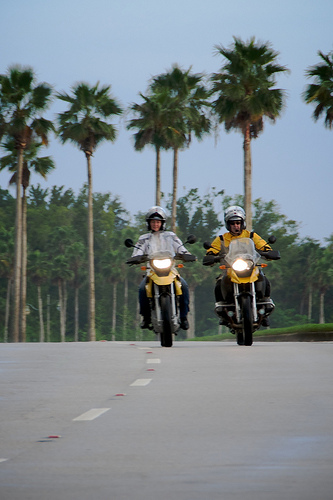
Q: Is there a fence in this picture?
A: No, there are no fences.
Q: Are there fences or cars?
A: No, there are no fences or cars.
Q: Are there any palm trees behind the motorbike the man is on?
A: Yes, there is a palm tree behind the motorcycle.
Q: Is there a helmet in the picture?
A: Yes, there is a helmet.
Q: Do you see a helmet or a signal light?
A: Yes, there is a helmet.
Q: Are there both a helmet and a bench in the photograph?
A: No, there is a helmet but no benches.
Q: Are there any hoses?
A: No, there are no hoses.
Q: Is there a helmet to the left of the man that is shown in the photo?
A: Yes, there is a helmet to the left of the man.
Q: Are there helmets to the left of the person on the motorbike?
A: Yes, there is a helmet to the left of the man.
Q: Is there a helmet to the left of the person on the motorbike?
A: Yes, there is a helmet to the left of the man.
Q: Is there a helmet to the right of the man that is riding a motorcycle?
A: No, the helmet is to the left of the man.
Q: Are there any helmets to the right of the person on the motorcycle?
A: No, the helmet is to the left of the man.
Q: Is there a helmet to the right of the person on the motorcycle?
A: No, the helmet is to the left of the man.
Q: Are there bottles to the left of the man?
A: No, there is a helmet to the left of the man.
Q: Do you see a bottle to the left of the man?
A: No, there is a helmet to the left of the man.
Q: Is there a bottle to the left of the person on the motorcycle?
A: No, there is a helmet to the left of the man.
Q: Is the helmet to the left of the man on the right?
A: Yes, the helmet is to the left of the man.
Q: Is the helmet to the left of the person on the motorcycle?
A: Yes, the helmet is to the left of the man.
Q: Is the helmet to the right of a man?
A: No, the helmet is to the left of a man.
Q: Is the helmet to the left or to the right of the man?
A: The helmet is to the left of the man.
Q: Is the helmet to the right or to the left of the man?
A: The helmet is to the left of the man.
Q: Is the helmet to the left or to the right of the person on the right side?
A: The helmet is to the left of the man.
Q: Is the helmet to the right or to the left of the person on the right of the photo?
A: The helmet is to the left of the man.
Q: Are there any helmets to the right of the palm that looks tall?
A: Yes, there is a helmet to the right of the palm.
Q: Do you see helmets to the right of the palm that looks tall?
A: Yes, there is a helmet to the right of the palm.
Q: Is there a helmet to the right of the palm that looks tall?
A: Yes, there is a helmet to the right of the palm.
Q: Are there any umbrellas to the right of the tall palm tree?
A: No, there is a helmet to the right of the palm tree.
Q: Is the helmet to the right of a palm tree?
A: Yes, the helmet is to the right of a palm tree.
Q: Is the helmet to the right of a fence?
A: No, the helmet is to the right of a palm tree.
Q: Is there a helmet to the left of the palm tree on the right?
A: Yes, there is a helmet to the left of the palm.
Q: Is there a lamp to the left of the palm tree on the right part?
A: No, there is a helmet to the left of the palm.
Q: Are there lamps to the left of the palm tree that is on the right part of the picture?
A: No, there is a helmet to the left of the palm.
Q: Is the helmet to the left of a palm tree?
A: Yes, the helmet is to the left of a palm tree.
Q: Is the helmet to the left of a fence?
A: No, the helmet is to the left of a palm tree.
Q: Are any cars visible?
A: No, there are no cars.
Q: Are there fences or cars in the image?
A: No, there are no cars or fences.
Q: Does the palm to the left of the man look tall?
A: Yes, the palm is tall.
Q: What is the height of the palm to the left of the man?
A: The palm tree is tall.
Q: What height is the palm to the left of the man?
A: The palm tree is tall.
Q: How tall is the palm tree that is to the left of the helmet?
A: The palm is tall.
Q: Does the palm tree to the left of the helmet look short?
A: No, the palm is tall.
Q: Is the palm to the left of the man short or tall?
A: The palm is tall.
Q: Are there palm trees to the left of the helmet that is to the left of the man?
A: Yes, there is a palm tree to the left of the helmet.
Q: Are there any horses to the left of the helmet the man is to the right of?
A: No, there is a palm tree to the left of the helmet.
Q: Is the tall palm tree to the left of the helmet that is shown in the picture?
A: Yes, the palm is to the left of the helmet.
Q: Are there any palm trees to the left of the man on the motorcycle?
A: Yes, there is a palm tree to the left of the man.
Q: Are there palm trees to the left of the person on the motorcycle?
A: Yes, there is a palm tree to the left of the man.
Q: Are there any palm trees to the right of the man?
A: No, the palm tree is to the left of the man.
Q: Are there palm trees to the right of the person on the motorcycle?
A: No, the palm tree is to the left of the man.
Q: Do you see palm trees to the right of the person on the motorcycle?
A: No, the palm tree is to the left of the man.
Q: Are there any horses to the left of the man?
A: No, there is a palm tree to the left of the man.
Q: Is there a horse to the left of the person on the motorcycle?
A: No, there is a palm tree to the left of the man.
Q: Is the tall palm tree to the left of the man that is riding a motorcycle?
A: Yes, the palm is to the left of the man.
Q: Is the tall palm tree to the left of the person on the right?
A: Yes, the palm is to the left of the man.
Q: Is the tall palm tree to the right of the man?
A: No, the palm tree is to the left of the man.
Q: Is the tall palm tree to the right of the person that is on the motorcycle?
A: No, the palm tree is to the left of the man.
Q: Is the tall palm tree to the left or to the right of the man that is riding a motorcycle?
A: The palm tree is to the left of the man.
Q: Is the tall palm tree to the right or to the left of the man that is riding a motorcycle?
A: The palm tree is to the left of the man.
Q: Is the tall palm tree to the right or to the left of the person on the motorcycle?
A: The palm tree is to the left of the man.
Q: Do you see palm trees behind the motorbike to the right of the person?
A: Yes, there is a palm tree behind the motorcycle.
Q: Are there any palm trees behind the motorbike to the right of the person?
A: Yes, there is a palm tree behind the motorcycle.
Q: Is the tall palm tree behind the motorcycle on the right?
A: Yes, the palm is behind the motorbike.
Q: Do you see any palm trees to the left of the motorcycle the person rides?
A: Yes, there is a palm tree to the left of the motorbike.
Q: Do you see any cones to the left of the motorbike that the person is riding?
A: No, there is a palm tree to the left of the motorbike.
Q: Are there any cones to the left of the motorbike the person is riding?
A: No, there is a palm tree to the left of the motorbike.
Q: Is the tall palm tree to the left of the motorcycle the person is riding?
A: Yes, the palm is to the left of the motorcycle.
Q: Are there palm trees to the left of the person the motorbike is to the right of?
A: Yes, there is a palm tree to the left of the person.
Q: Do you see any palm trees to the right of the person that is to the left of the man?
A: No, the palm tree is to the left of the person.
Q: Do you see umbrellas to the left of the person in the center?
A: No, there is a palm tree to the left of the person.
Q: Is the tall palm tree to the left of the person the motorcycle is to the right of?
A: Yes, the palm tree is to the left of the person.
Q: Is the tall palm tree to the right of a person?
A: No, the palm is to the left of a person.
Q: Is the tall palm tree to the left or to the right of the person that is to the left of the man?
A: The palm is to the left of the person.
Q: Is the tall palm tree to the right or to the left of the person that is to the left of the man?
A: The palm is to the left of the person.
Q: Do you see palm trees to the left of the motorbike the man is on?
A: Yes, there is a palm tree to the left of the motorcycle.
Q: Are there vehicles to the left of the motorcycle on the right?
A: No, there is a palm tree to the left of the motorbike.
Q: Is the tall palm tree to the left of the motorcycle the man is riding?
A: Yes, the palm is to the left of the motorbike.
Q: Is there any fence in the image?
A: No, there are no fences.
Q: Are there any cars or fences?
A: No, there are no fences or cars.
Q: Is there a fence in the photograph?
A: No, there are no fences.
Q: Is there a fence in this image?
A: No, there are no fences.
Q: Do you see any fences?
A: No, there are no fences.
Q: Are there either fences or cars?
A: No, there are no fences or cars.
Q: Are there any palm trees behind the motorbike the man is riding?
A: Yes, there is a palm tree behind the motorcycle.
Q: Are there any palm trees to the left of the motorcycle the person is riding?
A: Yes, there is a palm tree to the left of the motorcycle.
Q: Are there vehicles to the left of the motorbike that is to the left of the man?
A: No, there is a palm tree to the left of the motorbike.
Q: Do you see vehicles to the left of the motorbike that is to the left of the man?
A: No, there is a palm tree to the left of the motorbike.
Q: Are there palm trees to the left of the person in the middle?
A: Yes, there is a palm tree to the left of the person.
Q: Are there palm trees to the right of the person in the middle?
A: No, the palm tree is to the left of the person.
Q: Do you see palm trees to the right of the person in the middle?
A: No, the palm tree is to the left of the person.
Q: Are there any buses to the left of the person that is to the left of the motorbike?
A: No, there is a palm tree to the left of the person.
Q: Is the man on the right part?
A: Yes, the man is on the right of the image.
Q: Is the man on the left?
A: No, the man is on the right of the image.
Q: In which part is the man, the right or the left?
A: The man is on the right of the image.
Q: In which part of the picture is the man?
A: The man is on the right of the image.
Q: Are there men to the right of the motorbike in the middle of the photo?
A: Yes, there is a man to the right of the motorbike.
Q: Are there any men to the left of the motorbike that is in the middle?
A: No, the man is to the right of the motorbike.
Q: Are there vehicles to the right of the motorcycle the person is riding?
A: No, there is a man to the right of the motorcycle.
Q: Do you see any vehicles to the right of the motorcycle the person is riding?
A: No, there is a man to the right of the motorcycle.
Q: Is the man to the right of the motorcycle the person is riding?
A: Yes, the man is to the right of the motorcycle.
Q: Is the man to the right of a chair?
A: No, the man is to the right of the motorcycle.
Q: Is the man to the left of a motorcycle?
A: No, the man is to the right of a motorcycle.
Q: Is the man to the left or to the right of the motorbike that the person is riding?
A: The man is to the right of the motorbike.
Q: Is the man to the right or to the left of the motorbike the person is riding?
A: The man is to the right of the motorbike.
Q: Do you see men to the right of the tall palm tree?
A: Yes, there is a man to the right of the palm.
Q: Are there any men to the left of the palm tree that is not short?
A: No, the man is to the right of the palm.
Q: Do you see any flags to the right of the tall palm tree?
A: No, there is a man to the right of the palm.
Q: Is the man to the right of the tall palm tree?
A: Yes, the man is to the right of the palm tree.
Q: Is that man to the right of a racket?
A: No, the man is to the right of the palm tree.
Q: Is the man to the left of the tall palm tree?
A: No, the man is to the right of the palm tree.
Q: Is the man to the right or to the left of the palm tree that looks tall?
A: The man is to the right of the palm tree.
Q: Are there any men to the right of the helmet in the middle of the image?
A: Yes, there is a man to the right of the helmet.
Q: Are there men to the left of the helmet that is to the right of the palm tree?
A: No, the man is to the right of the helmet.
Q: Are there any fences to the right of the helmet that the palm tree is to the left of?
A: No, there is a man to the right of the helmet.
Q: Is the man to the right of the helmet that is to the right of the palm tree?
A: Yes, the man is to the right of the helmet.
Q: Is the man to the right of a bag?
A: No, the man is to the right of the helmet.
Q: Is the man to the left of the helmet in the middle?
A: No, the man is to the right of the helmet.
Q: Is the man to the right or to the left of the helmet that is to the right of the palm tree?
A: The man is to the right of the helmet.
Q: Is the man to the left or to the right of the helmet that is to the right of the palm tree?
A: The man is to the right of the helmet.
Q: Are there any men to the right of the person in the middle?
A: Yes, there is a man to the right of the person.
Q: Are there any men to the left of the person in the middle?
A: No, the man is to the right of the person.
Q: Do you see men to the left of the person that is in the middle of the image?
A: No, the man is to the right of the person.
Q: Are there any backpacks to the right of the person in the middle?
A: No, there is a man to the right of the person.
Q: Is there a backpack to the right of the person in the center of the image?
A: No, there is a man to the right of the person.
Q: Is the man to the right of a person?
A: Yes, the man is to the right of a person.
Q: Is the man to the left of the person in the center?
A: No, the man is to the right of the person.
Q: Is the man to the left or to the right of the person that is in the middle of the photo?
A: The man is to the right of the person.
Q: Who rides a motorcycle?
A: The man rides a motorcycle.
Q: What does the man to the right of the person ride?
A: The man rides a motorcycle.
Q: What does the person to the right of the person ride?
A: The man rides a motorcycle.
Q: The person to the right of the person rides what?
A: The man rides a motorcycle.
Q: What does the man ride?
A: The man rides a motorcycle.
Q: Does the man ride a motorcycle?
A: Yes, the man rides a motorcycle.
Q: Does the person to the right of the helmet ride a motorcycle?
A: Yes, the man rides a motorcycle.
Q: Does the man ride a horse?
A: No, the man rides a motorcycle.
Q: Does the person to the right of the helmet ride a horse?
A: No, the man rides a motorcycle.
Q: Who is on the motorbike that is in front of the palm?
A: The man is on the motorcycle.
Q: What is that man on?
A: The man is on the motorbike.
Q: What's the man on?
A: The man is on the motorbike.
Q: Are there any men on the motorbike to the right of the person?
A: Yes, there is a man on the motorcycle.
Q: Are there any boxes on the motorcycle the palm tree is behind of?
A: No, there is a man on the motorcycle.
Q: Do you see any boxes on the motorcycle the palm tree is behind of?
A: No, there is a man on the motorcycle.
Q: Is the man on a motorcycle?
A: Yes, the man is on a motorcycle.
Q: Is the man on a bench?
A: No, the man is on a motorcycle.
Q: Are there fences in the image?
A: No, there are no fences.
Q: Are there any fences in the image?
A: No, there are no fences.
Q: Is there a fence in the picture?
A: No, there are no fences.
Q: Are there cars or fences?
A: No, there are no fences or cars.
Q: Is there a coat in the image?
A: Yes, there is a coat.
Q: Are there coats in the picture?
A: Yes, there is a coat.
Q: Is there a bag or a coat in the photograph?
A: Yes, there is a coat.